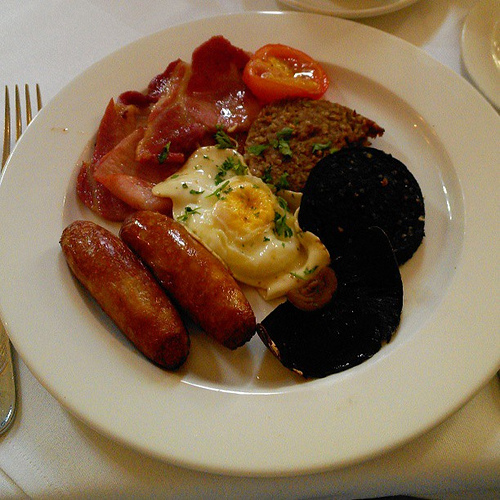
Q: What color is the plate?
A: White.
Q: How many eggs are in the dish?
A: One.